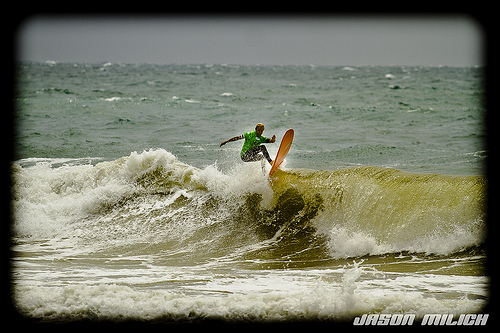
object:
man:
[219, 122, 276, 176]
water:
[56, 84, 210, 149]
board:
[268, 128, 295, 178]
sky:
[20, 14, 482, 72]